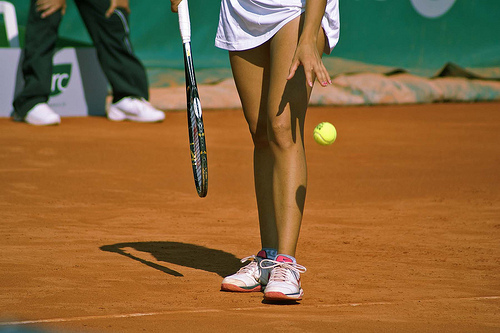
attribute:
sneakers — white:
[26, 94, 166, 125]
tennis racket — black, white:
[172, 2, 214, 197]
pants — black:
[10, 0, 149, 120]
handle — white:
[177, 0, 193, 41]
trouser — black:
[16, 6, 151, 123]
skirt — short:
[207, 0, 347, 60]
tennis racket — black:
[177, 1, 208, 196]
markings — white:
[14, 288, 496, 321]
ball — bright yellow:
[312, 117, 342, 153]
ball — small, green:
[309, 118, 344, 150]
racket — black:
[168, 8, 223, 200]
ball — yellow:
[305, 113, 340, 154]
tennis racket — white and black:
[176, 0, 219, 199]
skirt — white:
[212, 0, 340, 52]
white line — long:
[4, 297, 499, 329]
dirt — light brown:
[0, 117, 498, 328]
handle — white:
[173, 6, 193, 43]